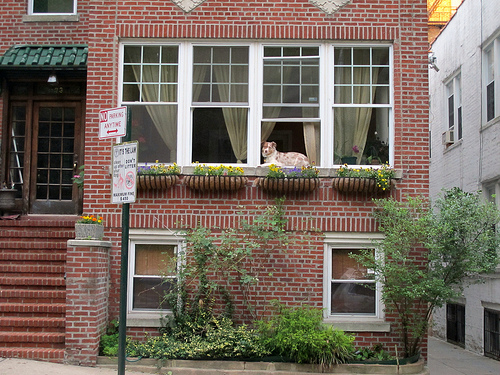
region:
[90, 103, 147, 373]
a sign on the street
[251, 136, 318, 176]
a dog on a window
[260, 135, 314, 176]
dog is brown and white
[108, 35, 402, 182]
a white window on a building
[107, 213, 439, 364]
bushes in front windows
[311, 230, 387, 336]
a window with white frame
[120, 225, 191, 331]
a window with white frame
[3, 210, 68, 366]
stairs of brick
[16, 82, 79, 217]
the front door of a home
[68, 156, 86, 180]
the handle of a door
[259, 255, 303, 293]
red brick on wall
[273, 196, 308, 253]
red brick on wall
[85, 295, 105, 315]
red brick on wall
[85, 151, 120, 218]
red brick on wall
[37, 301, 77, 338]
red brick on wall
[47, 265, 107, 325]
red brick on wall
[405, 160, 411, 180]
red brick on wall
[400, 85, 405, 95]
red brick on wall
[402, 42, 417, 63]
red brick on wall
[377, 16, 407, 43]
red brick on wall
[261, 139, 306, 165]
small white dog in the window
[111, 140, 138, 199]
white sign with black lettering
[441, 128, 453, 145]
air conditioner in window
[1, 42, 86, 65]
green overhang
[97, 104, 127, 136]
white sign with red letters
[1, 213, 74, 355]
red brick staircase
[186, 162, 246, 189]
flower box with only yellow flowers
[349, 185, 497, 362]
tall tree in front of the building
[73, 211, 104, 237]
gray rock planter with orange and yellow flowers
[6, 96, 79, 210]
door that is glass with dark wood trim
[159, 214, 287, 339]
over grown bush across window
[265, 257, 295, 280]
red bricks on the wall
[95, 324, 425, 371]
small plant bed in front of window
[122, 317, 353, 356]
green plants in plant bed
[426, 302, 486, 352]
small alley way besides house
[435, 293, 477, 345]
door in alley way building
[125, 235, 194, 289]
brown board on window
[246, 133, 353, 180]
large brown dog in window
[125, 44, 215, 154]
sheer yellow curtains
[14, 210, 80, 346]
steps leading up to the door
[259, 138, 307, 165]
a sitting brown and white dog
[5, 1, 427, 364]
a red brick building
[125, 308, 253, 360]
yellow flowers on a green bush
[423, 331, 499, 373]
alley between two buildings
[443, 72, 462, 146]
window with an air conditioner in it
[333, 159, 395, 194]
yellow flowers in a planter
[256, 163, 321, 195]
yellow, purple, and orange flowers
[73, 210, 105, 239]
yellow and orange flowers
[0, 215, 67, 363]
steps made out of brick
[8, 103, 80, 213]
wooden door with glass panes